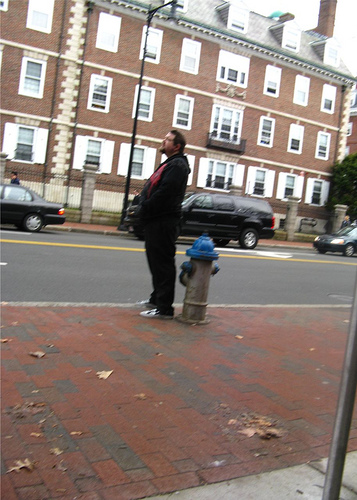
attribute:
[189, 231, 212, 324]
hydrant — blue, gray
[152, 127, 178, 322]
man — standing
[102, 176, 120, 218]
fence — metal, stone, black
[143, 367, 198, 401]
side walk — brick